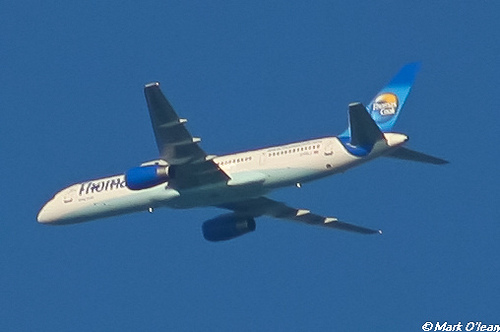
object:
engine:
[121, 158, 189, 191]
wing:
[143, 83, 231, 190]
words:
[109, 177, 120, 190]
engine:
[199, 210, 257, 242]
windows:
[246, 155, 252, 163]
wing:
[210, 195, 385, 235]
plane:
[37, 63, 451, 242]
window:
[267, 152, 272, 159]